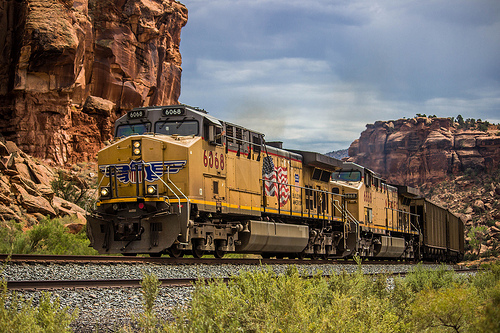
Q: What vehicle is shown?
A: Train.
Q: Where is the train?
A: In the desert.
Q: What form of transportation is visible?
A: Train.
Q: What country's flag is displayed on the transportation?
A: United States.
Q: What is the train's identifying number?
A: 6068.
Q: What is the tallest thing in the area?
A: Mountains.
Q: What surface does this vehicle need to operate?
A: Tracks.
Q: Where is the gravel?
A: Around the tracks.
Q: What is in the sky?
A: Clouds.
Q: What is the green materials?
A: Weeds.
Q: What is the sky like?
A: Blue with white clouds.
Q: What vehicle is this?
A: A train.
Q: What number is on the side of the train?
A: 6068.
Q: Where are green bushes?
A: On the sides of the tracks.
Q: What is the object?
A: Train.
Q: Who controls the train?
A: Conductor.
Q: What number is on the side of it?
A: 6068.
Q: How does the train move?
A: Train tracks.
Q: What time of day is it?
A: Day time.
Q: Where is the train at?
A: Canyon.